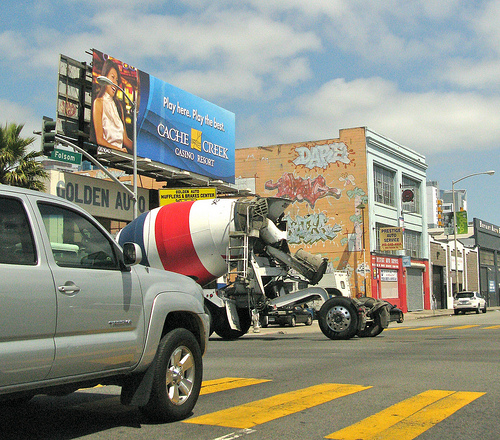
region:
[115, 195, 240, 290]
The red white and blue concrete mixer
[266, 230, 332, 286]
The concrete chute connected to the mixer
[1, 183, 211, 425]
The silver truck over the near crosswalk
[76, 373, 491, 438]
The crosswalk under the silver truck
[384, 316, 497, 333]
The crosswalk on the opposite side of the street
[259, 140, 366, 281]
The grafitti on the wall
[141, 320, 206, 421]
The front right tire of the silver truck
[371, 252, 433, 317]
The red store front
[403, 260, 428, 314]
The grey rollup door on the red store front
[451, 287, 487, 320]
The white car parked on the street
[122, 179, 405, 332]
A large cement mixer driving on the road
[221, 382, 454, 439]
Thick yellow lines painted on the road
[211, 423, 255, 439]
A small white line painted on the road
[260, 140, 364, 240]
Graffiti high up on the yellow wall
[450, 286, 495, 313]
A white van parked in the distance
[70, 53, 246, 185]
A large blue billboard above the road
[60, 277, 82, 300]
A small grey handle on the truck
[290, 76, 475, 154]
A fluffy white cloud in the sky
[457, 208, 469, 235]
A large green sign by the pole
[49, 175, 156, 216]
The sign says Golden Auto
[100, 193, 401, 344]
Cement mixer on the road.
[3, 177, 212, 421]
The truck is grey.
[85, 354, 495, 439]
Yellow crosswalk lines on the road.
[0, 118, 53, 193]
Tree behind the billboard.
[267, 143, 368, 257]
Graffiti on the building.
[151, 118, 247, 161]
Cache Creek on the billboard.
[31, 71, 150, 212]
Stoplight on a light pole.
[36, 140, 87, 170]
Street sign on the light pole.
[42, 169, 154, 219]
Golden Auto on the building.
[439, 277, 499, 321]
Car parked on the side of the road.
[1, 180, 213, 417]
a gray van on the street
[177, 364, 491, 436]
yellow lines on the road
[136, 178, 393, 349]
a cement mixer on the road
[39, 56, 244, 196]
a big advertising board on the roof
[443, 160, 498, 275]
a street light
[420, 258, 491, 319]
a white car in front a building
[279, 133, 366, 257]
graffiti on a brick wall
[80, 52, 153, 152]
a woman on a board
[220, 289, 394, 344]
wheels of a mixer machine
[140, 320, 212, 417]
front wheel of a car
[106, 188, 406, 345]
Large concrete mixer truck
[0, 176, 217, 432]
Vehicle on the road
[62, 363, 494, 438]
Yellow markings across the road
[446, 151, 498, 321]
Tall white street light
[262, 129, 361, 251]
Graffiti painting on a wall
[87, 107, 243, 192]
Large advertisement bill above a building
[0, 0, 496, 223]
Blue sky prinkled with white clouds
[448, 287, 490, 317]
White vehicle parked by the roadside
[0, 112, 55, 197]
Thin green tree leaves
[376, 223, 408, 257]
Sign hanging on the side of a wall